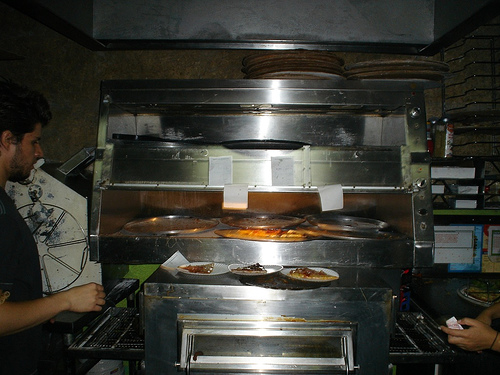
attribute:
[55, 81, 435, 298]
oven — large, metal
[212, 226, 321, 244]
pizza — cooking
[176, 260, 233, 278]
plate — round, white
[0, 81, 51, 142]
hair — brown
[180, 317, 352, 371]
door — clear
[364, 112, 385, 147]
ticket — taped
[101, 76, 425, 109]
roof — silver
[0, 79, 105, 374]
man — bearded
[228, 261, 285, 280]
plate — white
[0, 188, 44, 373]
shirt — black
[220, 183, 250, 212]
paper — white, hanging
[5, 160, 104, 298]
paper — white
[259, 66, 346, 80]
pan — stacked, used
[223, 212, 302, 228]
pizza — rotating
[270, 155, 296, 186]
order tag — hanging, white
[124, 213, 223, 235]
piece — metal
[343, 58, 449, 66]
object — found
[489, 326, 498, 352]
bracelet — black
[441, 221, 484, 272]
box — blue